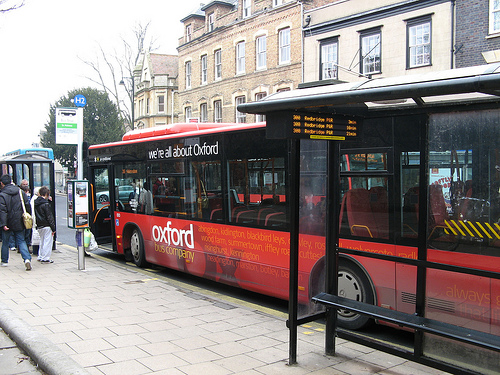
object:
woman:
[30, 186, 53, 258]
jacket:
[33, 196, 56, 232]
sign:
[292, 113, 357, 141]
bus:
[0, 147, 55, 195]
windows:
[315, 12, 434, 82]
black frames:
[316, 33, 341, 81]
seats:
[159, 182, 466, 252]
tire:
[129, 228, 149, 267]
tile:
[104, 323, 151, 337]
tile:
[113, 294, 149, 303]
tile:
[198, 329, 247, 344]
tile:
[11, 295, 48, 305]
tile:
[243, 346, 289, 365]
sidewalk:
[0, 240, 457, 374]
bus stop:
[0, 153, 57, 251]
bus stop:
[234, 62, 497, 375]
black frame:
[0, 160, 54, 250]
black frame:
[264, 105, 306, 139]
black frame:
[287, 109, 340, 364]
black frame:
[388, 113, 427, 153]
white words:
[151, 220, 195, 249]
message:
[148, 141, 219, 160]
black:
[94, 137, 266, 160]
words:
[292, 114, 357, 136]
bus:
[82, 95, 500, 353]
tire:
[317, 260, 374, 330]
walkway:
[28, 270, 222, 373]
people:
[0, 173, 34, 271]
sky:
[0, 0, 185, 102]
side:
[85, 120, 500, 355]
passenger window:
[223, 156, 288, 230]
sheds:
[236, 61, 500, 368]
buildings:
[129, 0, 500, 131]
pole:
[76, 107, 86, 271]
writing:
[152, 221, 195, 263]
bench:
[310, 291, 499, 375]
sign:
[68, 181, 89, 228]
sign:
[55, 94, 87, 144]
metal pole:
[76, 144, 83, 184]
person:
[34, 186, 57, 264]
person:
[17, 178, 35, 255]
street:
[71, 247, 409, 334]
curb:
[3, 234, 293, 371]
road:
[55, 192, 110, 256]